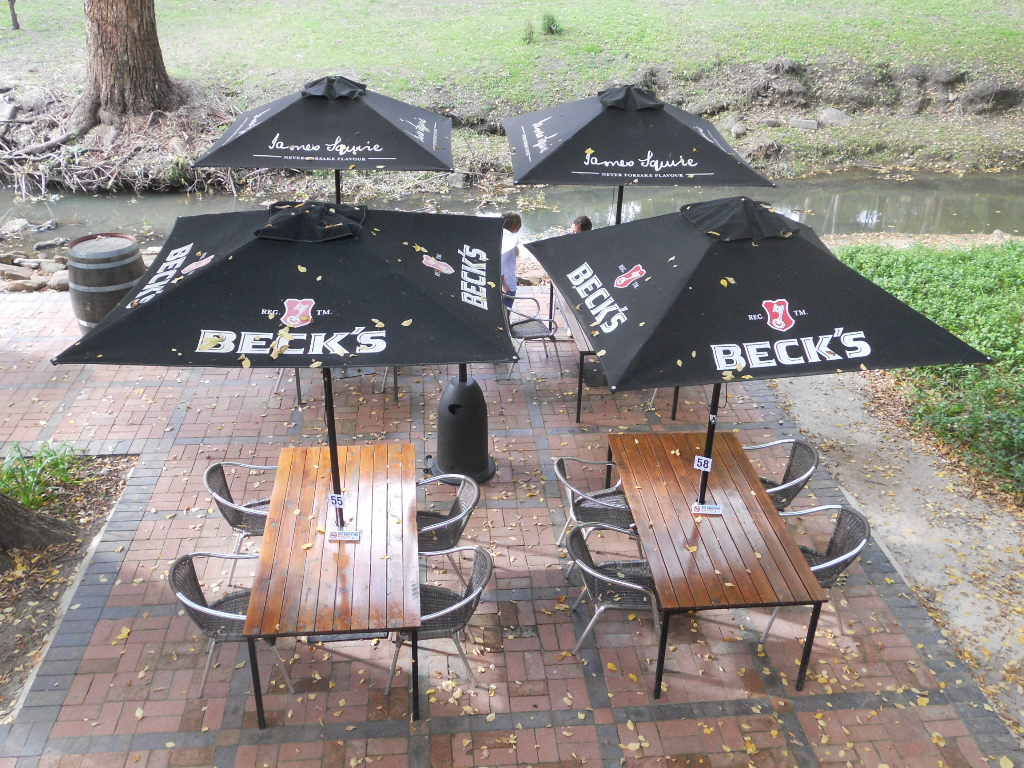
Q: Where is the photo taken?
A: In a restaurant.